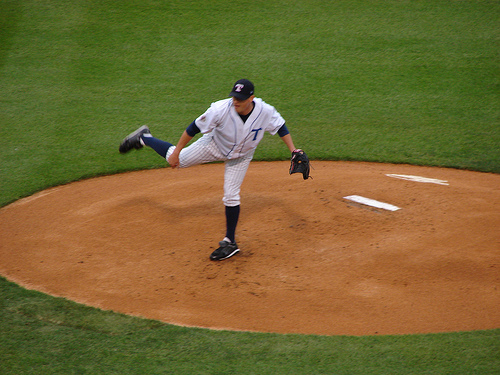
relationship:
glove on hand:
[282, 144, 325, 181] [239, 110, 328, 183]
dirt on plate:
[146, 214, 217, 272] [323, 173, 416, 236]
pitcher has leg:
[74, 46, 362, 298] [194, 175, 275, 268]